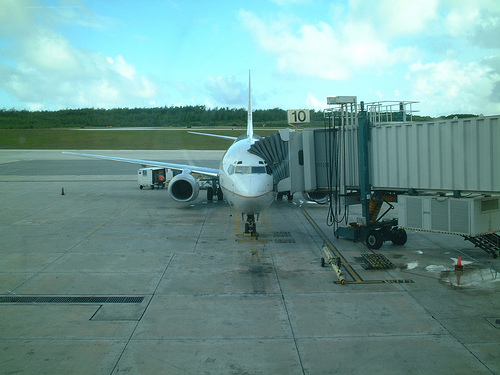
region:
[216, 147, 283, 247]
Head of an aircraft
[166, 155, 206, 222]
This is a fuselage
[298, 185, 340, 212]
This is a fuselage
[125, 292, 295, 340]
This is a tile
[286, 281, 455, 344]
This is a tile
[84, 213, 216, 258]
This is a tile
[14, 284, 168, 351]
This is a tile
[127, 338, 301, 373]
This is a tile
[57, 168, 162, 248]
This is a tile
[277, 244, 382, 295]
This is a tile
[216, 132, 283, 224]
This is an airplane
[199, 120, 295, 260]
This is an airplane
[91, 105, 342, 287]
This is an airplane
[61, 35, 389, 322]
This is an airplane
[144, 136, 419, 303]
This is an airplane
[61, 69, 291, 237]
A large parked plane.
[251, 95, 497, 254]
An object used for unloading passengers of a plane.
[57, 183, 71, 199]
A cone on the concrete.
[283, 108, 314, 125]
A rectangular sign with the number 10 on it.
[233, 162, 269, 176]
Front windows on a plane.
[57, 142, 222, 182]
A wing on a plane.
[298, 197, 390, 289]
A yellow and black t-shaped line.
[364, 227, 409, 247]
Two black wheels.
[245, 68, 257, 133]
The tail on a plane.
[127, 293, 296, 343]
A rectangular piece of concrete.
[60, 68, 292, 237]
airplane is docked at airport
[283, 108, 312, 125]
airport gate number 10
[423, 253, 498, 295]
orange cone in a puddle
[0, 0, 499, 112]
a cloudy blue sky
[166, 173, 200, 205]
engine of the plane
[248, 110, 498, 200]
the walkway to plane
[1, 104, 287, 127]
line of trees in background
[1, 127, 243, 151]
large field of green grass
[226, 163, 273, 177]
front windows of plane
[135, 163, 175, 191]
white van beside plane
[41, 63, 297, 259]
airplane at an airport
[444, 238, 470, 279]
orange cone on the ground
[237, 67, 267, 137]
tail on the airplane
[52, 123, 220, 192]
wing on the airplane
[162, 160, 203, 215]
engine on the airplane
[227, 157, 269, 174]
window on the airplane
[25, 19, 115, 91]
clouds in the sky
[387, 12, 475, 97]
clouds in the sky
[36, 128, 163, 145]
grass behind airport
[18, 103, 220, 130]
trees behind the airport